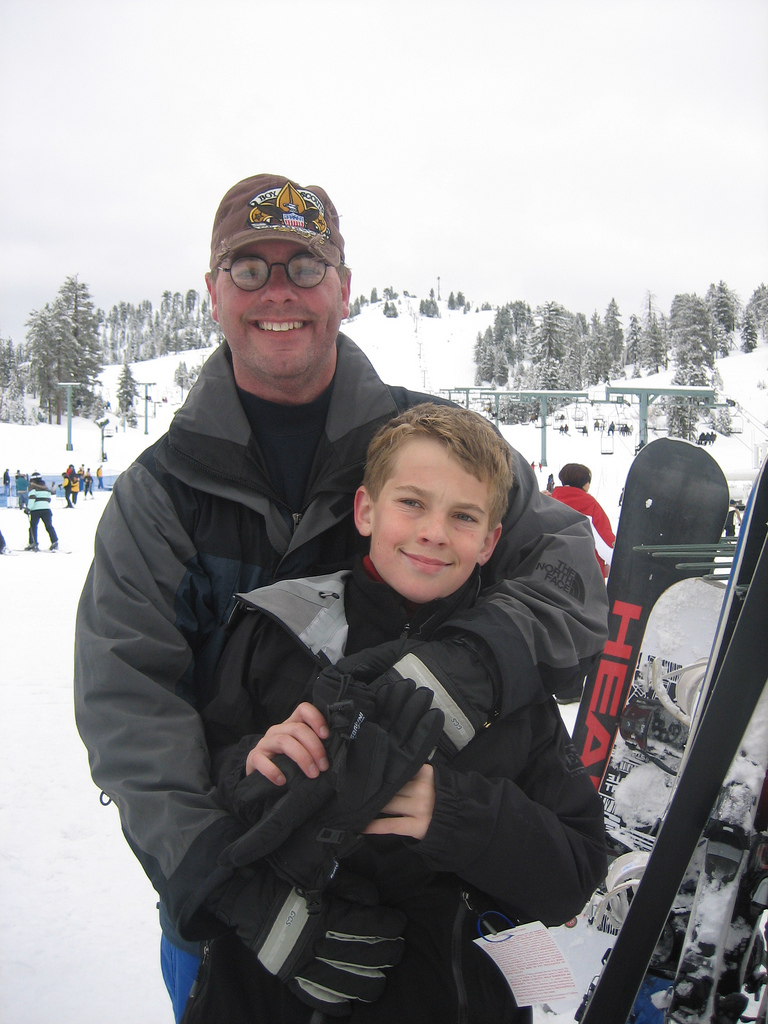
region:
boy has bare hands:
[229, 702, 360, 798]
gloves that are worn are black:
[199, 824, 426, 1005]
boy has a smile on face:
[387, 534, 476, 589]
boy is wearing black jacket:
[263, 577, 551, 1022]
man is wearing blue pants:
[148, 889, 208, 1017]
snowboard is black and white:
[592, 558, 764, 995]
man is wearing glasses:
[220, 255, 342, 293]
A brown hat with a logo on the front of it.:
[207, 172, 347, 272]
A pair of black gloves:
[228, 670, 443, 912]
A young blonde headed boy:
[181, 397, 607, 1022]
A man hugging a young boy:
[72, 173, 611, 1022]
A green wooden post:
[59, 381, 84, 449]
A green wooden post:
[138, 382, 154, 434]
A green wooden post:
[517, 389, 589, 463]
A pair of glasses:
[204, 252, 341, 290]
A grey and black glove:
[205, 859, 407, 1016]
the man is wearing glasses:
[149, 175, 373, 379]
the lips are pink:
[369, 532, 477, 590]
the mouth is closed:
[360, 541, 479, 624]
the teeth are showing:
[220, 298, 338, 363]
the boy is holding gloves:
[186, 678, 462, 864]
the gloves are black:
[260, 657, 483, 864]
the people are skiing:
[10, 366, 187, 586]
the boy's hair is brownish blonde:
[326, 380, 525, 525]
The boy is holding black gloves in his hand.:
[280, 672, 411, 846]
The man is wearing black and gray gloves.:
[241, 893, 397, 998]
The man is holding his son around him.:
[140, 202, 588, 762]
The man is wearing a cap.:
[213, 180, 340, 248]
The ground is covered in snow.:
[25, 752, 163, 1021]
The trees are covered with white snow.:
[486, 304, 713, 379]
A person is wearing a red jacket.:
[546, 488, 604, 532]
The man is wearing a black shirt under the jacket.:
[255, 385, 318, 481]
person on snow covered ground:
[22, 469, 63, 552]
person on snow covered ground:
[58, 461, 82, 513]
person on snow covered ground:
[1, 466, 17, 491]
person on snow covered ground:
[11, 468, 25, 505]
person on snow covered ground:
[81, 466, 94, 498]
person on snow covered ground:
[92, 462, 106, 492]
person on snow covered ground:
[548, 462, 616, 585]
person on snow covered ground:
[525, 460, 539, 475]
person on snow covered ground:
[205, 402, 607, 1022]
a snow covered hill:
[347, 293, 495, 386]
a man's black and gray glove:
[211, 875, 411, 1005]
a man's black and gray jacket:
[60, 324, 627, 941]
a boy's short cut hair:
[359, 399, 519, 538]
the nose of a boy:
[418, 501, 455, 548]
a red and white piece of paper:
[469, 915, 579, 1009]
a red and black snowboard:
[576, 431, 747, 924]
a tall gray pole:
[57, 374, 85, 449]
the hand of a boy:
[247, 694, 339, 787]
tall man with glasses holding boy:
[73, 176, 614, 1022]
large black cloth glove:
[269, 673, 446, 899]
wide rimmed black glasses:
[209, 255, 345, 289]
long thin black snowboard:
[568, 435, 732, 790]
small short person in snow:
[20, 468, 62, 551]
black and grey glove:
[210, 863, 423, 1016]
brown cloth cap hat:
[206, 173, 347, 276]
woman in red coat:
[545, 461, 620, 577]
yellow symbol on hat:
[246, 182, 334, 244]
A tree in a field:
[112, 359, 142, 423]